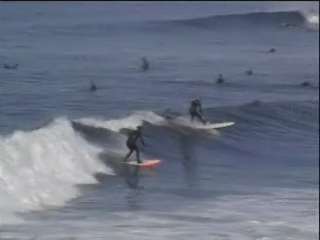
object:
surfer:
[122, 125, 149, 164]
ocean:
[1, 0, 319, 240]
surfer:
[187, 97, 210, 128]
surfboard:
[121, 158, 162, 167]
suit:
[122, 129, 148, 163]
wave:
[0, 110, 169, 226]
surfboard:
[190, 120, 236, 130]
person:
[140, 55, 150, 71]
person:
[216, 73, 225, 85]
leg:
[194, 113, 209, 126]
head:
[136, 124, 144, 131]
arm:
[138, 135, 147, 148]